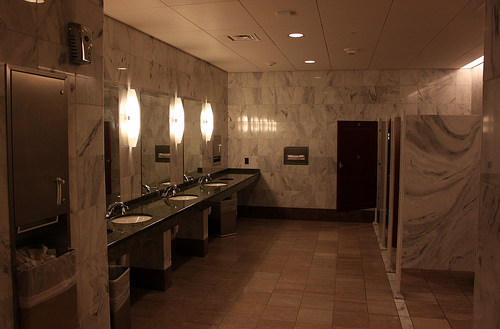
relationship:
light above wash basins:
[124, 88, 140, 147] [106, 164, 261, 255]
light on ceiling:
[304, 55, 316, 66] [363, 2, 463, 69]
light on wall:
[124, 88, 147, 159] [102, 14, 222, 211]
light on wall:
[198, 94, 217, 146] [257, 77, 336, 120]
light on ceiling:
[283, 24, 313, 45] [168, 12, 415, 75]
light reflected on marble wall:
[236, 112, 279, 133] [226, 67, 471, 206]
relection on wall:
[229, 108, 285, 138] [228, 73, 474, 227]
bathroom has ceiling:
[7, 2, 495, 324] [126, 1, 481, 65]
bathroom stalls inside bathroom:
[381, 110, 498, 298] [28, 14, 495, 316]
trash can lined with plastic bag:
[217, 198, 238, 235] [212, 199, 235, 211]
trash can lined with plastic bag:
[105, 261, 134, 327] [110, 263, 132, 308]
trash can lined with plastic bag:
[15, 242, 80, 327] [10, 248, 80, 305]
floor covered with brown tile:
[118, 215, 486, 326] [282, 218, 315, 327]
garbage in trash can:
[3, 229, 80, 266] [4, 236, 97, 327]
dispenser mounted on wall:
[283, 145, 309, 165] [228, 73, 474, 227]